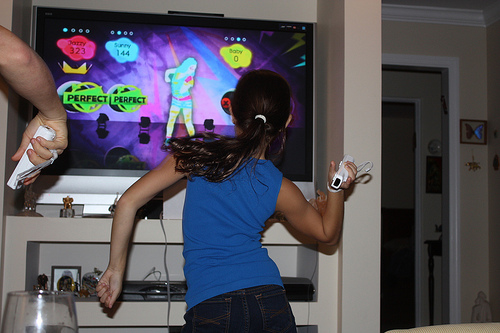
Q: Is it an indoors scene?
A: Yes, it is indoors.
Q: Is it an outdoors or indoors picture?
A: It is indoors.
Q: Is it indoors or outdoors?
A: It is indoors.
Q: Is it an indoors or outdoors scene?
A: It is indoors.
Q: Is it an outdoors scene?
A: No, it is indoors.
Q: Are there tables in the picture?
A: Yes, there is a table.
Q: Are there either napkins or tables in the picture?
A: Yes, there is a table.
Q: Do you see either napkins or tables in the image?
A: Yes, there is a table.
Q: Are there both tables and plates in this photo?
A: No, there is a table but no plates.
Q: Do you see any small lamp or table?
A: Yes, there is a small table.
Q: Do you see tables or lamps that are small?
A: Yes, the table is small.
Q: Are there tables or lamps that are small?
A: Yes, the table is small.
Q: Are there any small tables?
A: Yes, there is a small table.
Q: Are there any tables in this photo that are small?
A: Yes, there is a small table.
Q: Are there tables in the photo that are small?
A: Yes, there is a table that is small.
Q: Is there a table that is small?
A: Yes, there is a table that is small.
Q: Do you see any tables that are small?
A: Yes, there is a table that is small.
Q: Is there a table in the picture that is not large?
A: Yes, there is a small table.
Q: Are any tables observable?
A: Yes, there is a table.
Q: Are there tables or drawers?
A: Yes, there is a table.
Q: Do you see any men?
A: No, there are no men.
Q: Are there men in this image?
A: No, there are no men.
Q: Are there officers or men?
A: No, there are no men or officers.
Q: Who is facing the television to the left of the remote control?
A: The girl is facing the television.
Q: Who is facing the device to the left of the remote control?
A: The girl is facing the television.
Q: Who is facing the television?
A: The girl is facing the television.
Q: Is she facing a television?
A: Yes, the girl is facing a television.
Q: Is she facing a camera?
A: No, the girl is facing a television.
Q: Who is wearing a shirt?
A: The girl is wearing a shirt.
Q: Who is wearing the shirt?
A: The girl is wearing a shirt.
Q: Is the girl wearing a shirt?
A: Yes, the girl is wearing a shirt.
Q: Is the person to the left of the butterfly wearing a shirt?
A: Yes, the girl is wearing a shirt.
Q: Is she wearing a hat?
A: No, the girl is wearing a shirt.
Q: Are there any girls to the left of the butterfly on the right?
A: Yes, there is a girl to the left of the butterfly.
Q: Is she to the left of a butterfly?
A: Yes, the girl is to the left of a butterfly.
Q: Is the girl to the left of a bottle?
A: No, the girl is to the left of a butterfly.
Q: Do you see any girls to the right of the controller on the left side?
A: Yes, there is a girl to the right of the controller.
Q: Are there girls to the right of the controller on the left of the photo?
A: Yes, there is a girl to the right of the controller.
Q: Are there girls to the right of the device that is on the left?
A: Yes, there is a girl to the right of the controller.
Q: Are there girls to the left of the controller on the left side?
A: No, the girl is to the right of the controller.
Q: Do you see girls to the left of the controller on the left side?
A: No, the girl is to the right of the controller.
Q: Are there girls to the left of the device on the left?
A: No, the girl is to the right of the controller.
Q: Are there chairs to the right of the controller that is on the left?
A: No, there is a girl to the right of the controller.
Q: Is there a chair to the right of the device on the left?
A: No, there is a girl to the right of the controller.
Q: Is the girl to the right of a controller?
A: Yes, the girl is to the right of a controller.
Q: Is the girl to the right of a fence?
A: No, the girl is to the right of a controller.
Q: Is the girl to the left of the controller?
A: No, the girl is to the right of the controller.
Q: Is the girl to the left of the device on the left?
A: No, the girl is to the right of the controller.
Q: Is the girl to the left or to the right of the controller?
A: The girl is to the right of the controller.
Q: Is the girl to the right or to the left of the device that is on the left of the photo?
A: The girl is to the right of the controller.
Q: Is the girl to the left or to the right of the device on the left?
A: The girl is to the right of the controller.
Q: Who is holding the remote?
A: The girl is holding the remote.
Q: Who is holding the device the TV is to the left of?
A: The girl is holding the remote.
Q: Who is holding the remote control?
A: The girl is holding the remote.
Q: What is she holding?
A: The girl is holding the remote control.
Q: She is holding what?
A: The girl is holding the remote control.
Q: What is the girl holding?
A: The girl is holding the remote control.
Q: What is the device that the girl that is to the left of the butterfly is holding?
A: The device is a remote control.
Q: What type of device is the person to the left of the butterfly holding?
A: The girl is holding the remote.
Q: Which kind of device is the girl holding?
A: The girl is holding the remote.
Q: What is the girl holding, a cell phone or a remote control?
A: The girl is holding a remote control.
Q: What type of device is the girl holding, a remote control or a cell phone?
A: The girl is holding a remote control.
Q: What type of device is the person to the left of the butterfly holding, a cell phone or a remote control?
A: The girl is holding a remote control.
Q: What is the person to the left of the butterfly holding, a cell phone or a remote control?
A: The girl is holding a remote control.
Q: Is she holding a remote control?
A: Yes, the girl is holding a remote control.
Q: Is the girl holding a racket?
A: No, the girl is holding a remote control.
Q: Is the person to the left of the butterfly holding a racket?
A: No, the girl is holding a remote control.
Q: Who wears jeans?
A: The girl wears jeans.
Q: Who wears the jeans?
A: The girl wears jeans.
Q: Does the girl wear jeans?
A: Yes, the girl wears jeans.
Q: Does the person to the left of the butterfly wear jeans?
A: Yes, the girl wears jeans.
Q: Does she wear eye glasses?
A: No, the girl wears jeans.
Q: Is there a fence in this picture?
A: No, there are no fences.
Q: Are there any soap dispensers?
A: No, there are no soap dispensers.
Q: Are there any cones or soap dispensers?
A: No, there are no soap dispensers or cones.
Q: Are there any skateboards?
A: No, there are no skateboards.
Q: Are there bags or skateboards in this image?
A: No, there are no skateboards or bags.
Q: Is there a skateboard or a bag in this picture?
A: No, there are no skateboards or bags.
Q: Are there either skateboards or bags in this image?
A: No, there are no skateboards or bags.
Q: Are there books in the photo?
A: No, there are no books.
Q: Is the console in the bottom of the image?
A: Yes, the console is in the bottom of the image.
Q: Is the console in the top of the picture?
A: No, the console is in the bottom of the image.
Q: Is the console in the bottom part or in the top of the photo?
A: The console is in the bottom of the image.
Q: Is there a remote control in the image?
A: Yes, there is a remote control.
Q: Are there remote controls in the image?
A: Yes, there is a remote control.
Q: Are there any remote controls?
A: Yes, there is a remote control.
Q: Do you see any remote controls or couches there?
A: Yes, there is a remote control.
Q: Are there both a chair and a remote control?
A: No, there is a remote control but no chairs.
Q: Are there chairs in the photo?
A: No, there are no chairs.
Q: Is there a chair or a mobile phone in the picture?
A: No, there are no chairs or cell phones.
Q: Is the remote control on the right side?
A: Yes, the remote control is on the right of the image.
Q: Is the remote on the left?
A: No, the remote is on the right of the image.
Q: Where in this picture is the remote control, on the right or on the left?
A: The remote control is on the right of the image.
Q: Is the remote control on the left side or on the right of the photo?
A: The remote control is on the right of the image.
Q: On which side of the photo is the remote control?
A: The remote control is on the right of the image.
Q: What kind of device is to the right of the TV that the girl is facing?
A: The device is a remote control.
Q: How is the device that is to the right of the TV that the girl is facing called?
A: The device is a remote control.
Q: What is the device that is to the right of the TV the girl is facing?
A: The device is a remote control.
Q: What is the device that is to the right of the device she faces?
A: The device is a remote control.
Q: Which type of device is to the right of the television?
A: The device is a remote control.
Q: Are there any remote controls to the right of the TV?
A: Yes, there is a remote control to the right of the TV.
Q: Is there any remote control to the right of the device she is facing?
A: Yes, there is a remote control to the right of the TV.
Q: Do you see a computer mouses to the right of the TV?
A: No, there is a remote control to the right of the TV.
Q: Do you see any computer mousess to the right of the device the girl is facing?
A: No, there is a remote control to the right of the TV.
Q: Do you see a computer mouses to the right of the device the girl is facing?
A: No, there is a remote control to the right of the TV.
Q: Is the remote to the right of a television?
A: Yes, the remote is to the right of a television.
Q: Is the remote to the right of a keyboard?
A: No, the remote is to the right of a television.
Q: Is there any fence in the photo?
A: No, there are no fences.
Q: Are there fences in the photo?
A: No, there are no fences.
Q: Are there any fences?
A: No, there are no fences.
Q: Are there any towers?
A: No, there are no towers.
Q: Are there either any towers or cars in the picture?
A: No, there are no towers or cars.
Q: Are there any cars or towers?
A: No, there are no towers or cars.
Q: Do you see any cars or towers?
A: No, there are no towers or cars.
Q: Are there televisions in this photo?
A: Yes, there is a television.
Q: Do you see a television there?
A: Yes, there is a television.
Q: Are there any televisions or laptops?
A: Yes, there is a television.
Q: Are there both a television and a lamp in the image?
A: No, there is a television but no lamps.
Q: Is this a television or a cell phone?
A: This is a television.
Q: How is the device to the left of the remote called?
A: The device is a television.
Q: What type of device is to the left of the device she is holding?
A: The device is a television.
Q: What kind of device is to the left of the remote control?
A: The device is a television.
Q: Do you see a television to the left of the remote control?
A: Yes, there is a television to the left of the remote control.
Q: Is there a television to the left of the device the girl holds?
A: Yes, there is a television to the left of the remote control.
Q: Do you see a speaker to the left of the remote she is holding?
A: No, there is a television to the left of the remote control.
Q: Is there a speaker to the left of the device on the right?
A: No, there is a television to the left of the remote control.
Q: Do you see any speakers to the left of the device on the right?
A: No, there is a television to the left of the remote control.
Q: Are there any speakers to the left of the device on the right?
A: No, there is a television to the left of the remote control.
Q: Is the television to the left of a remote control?
A: Yes, the television is to the left of a remote control.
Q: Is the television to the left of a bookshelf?
A: No, the television is to the left of a remote control.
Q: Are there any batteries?
A: No, there are no batteries.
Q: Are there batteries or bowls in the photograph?
A: No, there are no batteries or bowls.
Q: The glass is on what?
A: The glass is on the table.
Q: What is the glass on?
A: The glass is on the table.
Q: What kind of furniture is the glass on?
A: The glass is on the table.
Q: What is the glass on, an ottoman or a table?
A: The glass is on a table.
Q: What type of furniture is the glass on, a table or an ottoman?
A: The glass is on a table.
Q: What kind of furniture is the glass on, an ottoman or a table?
A: The glass is on a table.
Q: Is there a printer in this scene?
A: No, there are no printers.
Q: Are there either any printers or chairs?
A: No, there are no printers or chairs.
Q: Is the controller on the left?
A: Yes, the controller is on the left of the image.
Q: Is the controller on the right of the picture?
A: No, the controller is on the left of the image.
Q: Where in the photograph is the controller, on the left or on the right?
A: The controller is on the left of the image.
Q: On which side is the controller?
A: The controller is on the left of the image.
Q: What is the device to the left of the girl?
A: The device is a controller.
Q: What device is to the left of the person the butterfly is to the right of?
A: The device is a controller.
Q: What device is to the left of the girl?
A: The device is a controller.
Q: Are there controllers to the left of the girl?
A: Yes, there is a controller to the left of the girl.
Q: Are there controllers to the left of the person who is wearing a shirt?
A: Yes, there is a controller to the left of the girl.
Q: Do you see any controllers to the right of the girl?
A: No, the controller is to the left of the girl.